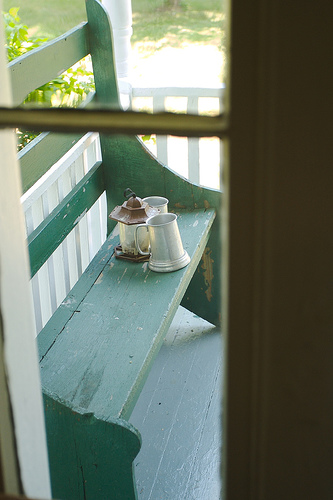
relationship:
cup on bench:
[133, 206, 189, 270] [7, 0, 220, 499]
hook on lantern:
[123, 188, 135, 197] [108, 196, 148, 261]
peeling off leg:
[199, 243, 217, 304] [120, 132, 221, 327]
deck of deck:
[128, 305, 233, 497] [37, 50, 246, 283]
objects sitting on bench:
[112, 182, 196, 270] [7, 0, 220, 499]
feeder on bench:
[108, 191, 159, 264] [7, 0, 220, 499]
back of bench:
[6, 21, 108, 286] [10, 19, 107, 355]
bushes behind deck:
[1, 2, 83, 96] [3, 83, 227, 494]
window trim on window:
[0, 106, 229, 139] [0, 1, 232, 498]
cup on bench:
[125, 204, 208, 271] [7, 0, 220, 499]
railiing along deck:
[131, 83, 224, 118] [162, 333, 217, 482]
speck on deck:
[157, 401, 160, 405] [129, 304, 223, 498]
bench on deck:
[7, 0, 220, 499] [129, 304, 223, 498]